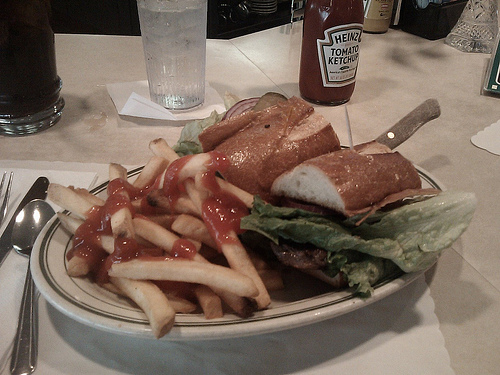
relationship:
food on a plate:
[58, 101, 475, 324] [30, 154, 452, 344]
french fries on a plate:
[46, 137, 271, 339] [30, 154, 452, 344]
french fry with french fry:
[106, 259, 258, 299] [109, 276, 177, 338]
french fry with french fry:
[106, 259, 258, 299] [189, 178, 273, 309]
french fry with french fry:
[106, 259, 258, 299] [46, 184, 96, 219]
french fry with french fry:
[106, 259, 258, 299] [103, 160, 135, 242]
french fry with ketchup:
[106, 259, 258, 299] [66, 155, 248, 287]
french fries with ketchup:
[46, 137, 271, 339] [197, 175, 249, 242]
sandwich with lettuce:
[182, 86, 444, 272] [259, 221, 452, 277]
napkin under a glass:
[107, 73, 227, 120] [136, 0, 208, 112]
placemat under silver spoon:
[0, 158, 451, 375] [11, 199, 58, 375]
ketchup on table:
[294, 5, 376, 112] [0, 16, 482, 373]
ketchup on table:
[298, 0, 364, 107] [0, 16, 482, 373]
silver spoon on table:
[11, 199, 58, 375] [0, 16, 482, 373]